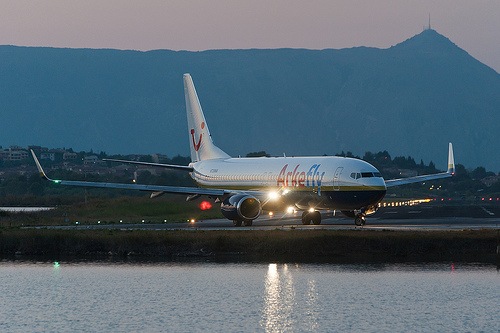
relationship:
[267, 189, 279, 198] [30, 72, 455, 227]
light behind plane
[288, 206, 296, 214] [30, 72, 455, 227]
light behind plane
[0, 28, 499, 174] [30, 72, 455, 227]
mountain behind plane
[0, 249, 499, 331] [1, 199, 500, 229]
water near runway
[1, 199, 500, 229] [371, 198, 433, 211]
runway with lights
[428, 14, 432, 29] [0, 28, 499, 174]
tower on mountain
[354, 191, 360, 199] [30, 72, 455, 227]
headlights on plane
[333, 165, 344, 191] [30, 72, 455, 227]
door on side of plane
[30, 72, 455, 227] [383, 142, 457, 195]
plane has a wing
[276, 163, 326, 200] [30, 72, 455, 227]
words on plane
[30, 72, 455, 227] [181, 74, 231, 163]
plane has a tail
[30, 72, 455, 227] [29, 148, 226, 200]
plane has a wing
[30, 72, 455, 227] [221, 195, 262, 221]
plane has an engine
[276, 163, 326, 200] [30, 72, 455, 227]
words on side of plane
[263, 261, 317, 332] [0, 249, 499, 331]
reflection on top of water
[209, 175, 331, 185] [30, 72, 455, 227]
windows on side of plane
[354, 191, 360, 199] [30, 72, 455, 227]
headlights in front of plane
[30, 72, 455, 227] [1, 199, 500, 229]
plane on top of runway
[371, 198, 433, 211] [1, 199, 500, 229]
lights on top of runway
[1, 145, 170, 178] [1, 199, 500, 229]
area behind runway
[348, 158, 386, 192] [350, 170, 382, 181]
cockpit with windows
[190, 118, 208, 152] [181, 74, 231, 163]
logo on planes tail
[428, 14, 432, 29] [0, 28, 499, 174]
tower on top of mountain